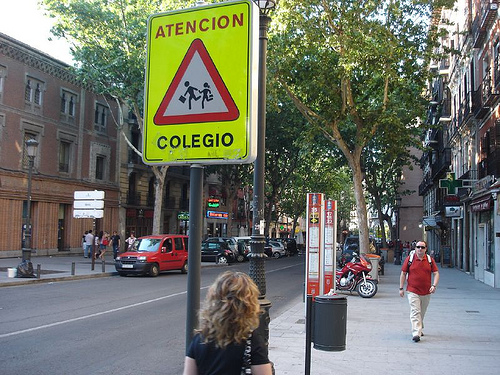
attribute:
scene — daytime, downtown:
[1, 1, 486, 369]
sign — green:
[437, 178, 468, 189]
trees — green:
[38, 1, 461, 213]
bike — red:
[334, 250, 378, 300]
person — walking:
[397, 236, 440, 344]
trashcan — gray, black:
[315, 294, 348, 351]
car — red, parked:
[116, 235, 191, 276]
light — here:
[23, 141, 37, 285]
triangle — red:
[151, 43, 242, 128]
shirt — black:
[186, 327, 268, 374]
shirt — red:
[401, 251, 440, 295]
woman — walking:
[184, 261, 281, 374]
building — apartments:
[1, 37, 191, 262]